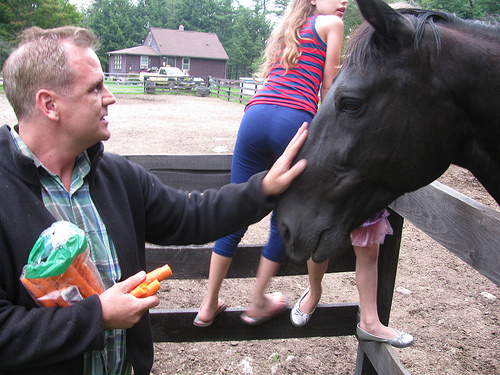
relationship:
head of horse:
[260, 1, 465, 270] [260, 1, 500, 264]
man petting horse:
[2, 19, 318, 374] [260, 1, 500, 264]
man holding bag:
[2, 19, 318, 374] [17, 216, 114, 315]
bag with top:
[17, 216, 114, 315] [14, 219, 90, 285]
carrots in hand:
[126, 255, 175, 306] [95, 264, 164, 335]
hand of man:
[95, 264, 164, 335] [2, 19, 318, 374]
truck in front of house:
[137, 63, 192, 93] [103, 19, 234, 87]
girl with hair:
[193, 2, 350, 330] [247, 2, 312, 85]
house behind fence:
[103, 19, 234, 87] [1, 70, 263, 107]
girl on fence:
[193, 2, 350, 330] [1, 70, 263, 107]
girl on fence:
[290, 187, 416, 349] [1, 70, 263, 107]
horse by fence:
[260, 1, 500, 264] [1, 143, 500, 374]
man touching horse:
[2, 19, 318, 374] [260, 1, 500, 264]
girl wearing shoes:
[290, 187, 416, 349] [356, 321, 417, 351]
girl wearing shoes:
[290, 187, 416, 349] [287, 280, 324, 330]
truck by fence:
[137, 63, 192, 93] [1, 70, 263, 107]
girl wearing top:
[193, 2, 350, 330] [238, 10, 329, 127]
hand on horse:
[262, 121, 317, 193] [260, 1, 500, 264]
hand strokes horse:
[262, 121, 317, 193] [260, 1, 500, 264]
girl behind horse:
[290, 187, 416, 349] [260, 1, 500, 264]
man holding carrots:
[2, 19, 318, 374] [126, 255, 175, 306]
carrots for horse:
[126, 255, 175, 306] [260, 1, 500, 264]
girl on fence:
[193, 2, 350, 330] [1, 143, 500, 374]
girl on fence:
[290, 187, 416, 349] [1, 143, 500, 374]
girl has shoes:
[290, 187, 416, 349] [356, 321, 417, 351]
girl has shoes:
[290, 187, 416, 349] [287, 280, 324, 330]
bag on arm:
[17, 216, 114, 315] [2, 292, 108, 363]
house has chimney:
[103, 19, 234, 87] [176, 22, 187, 34]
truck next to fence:
[137, 63, 192, 93] [1, 70, 263, 107]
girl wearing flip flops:
[193, 2, 350, 330] [242, 290, 288, 325]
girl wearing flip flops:
[193, 2, 350, 330] [190, 290, 230, 327]